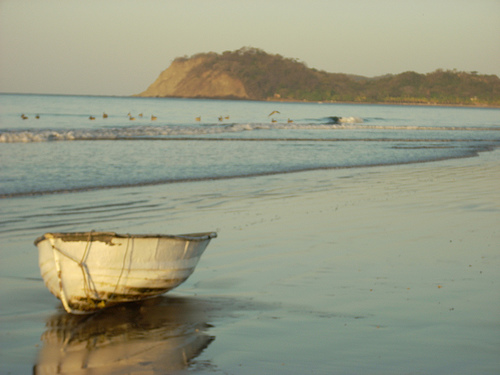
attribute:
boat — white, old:
[35, 219, 220, 315]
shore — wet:
[0, 149, 498, 374]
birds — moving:
[17, 107, 298, 129]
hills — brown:
[137, 48, 499, 104]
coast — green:
[3, 148, 499, 197]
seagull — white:
[269, 109, 281, 121]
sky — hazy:
[2, 0, 499, 95]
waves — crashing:
[1, 121, 352, 144]